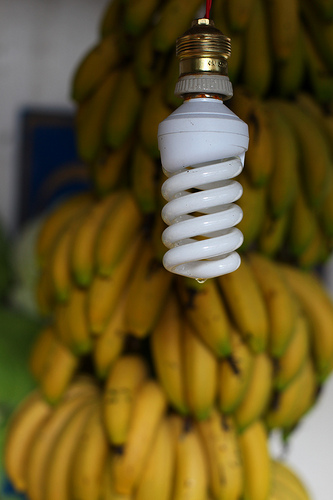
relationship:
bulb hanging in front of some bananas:
[158, 98, 248, 279] [12, 6, 329, 497]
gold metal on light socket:
[176, 17, 231, 75] [175, 17, 230, 76]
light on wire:
[156, 17, 248, 284] [193, 6, 214, 19]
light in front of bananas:
[161, 19, 251, 286] [12, 6, 329, 497]